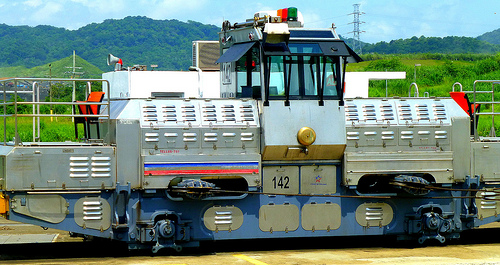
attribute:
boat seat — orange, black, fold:
[69, 88, 107, 142]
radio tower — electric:
[337, 1, 372, 62]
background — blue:
[4, 0, 498, 51]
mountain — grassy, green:
[354, 52, 497, 98]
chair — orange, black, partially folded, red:
[447, 85, 486, 138]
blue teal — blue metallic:
[212, 40, 260, 65]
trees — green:
[375, 33, 485, 57]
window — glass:
[231, 42, 349, 99]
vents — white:
[143, 100, 450, 152]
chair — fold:
[67, 89, 108, 139]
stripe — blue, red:
[142, 159, 263, 178]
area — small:
[219, 39, 348, 100]